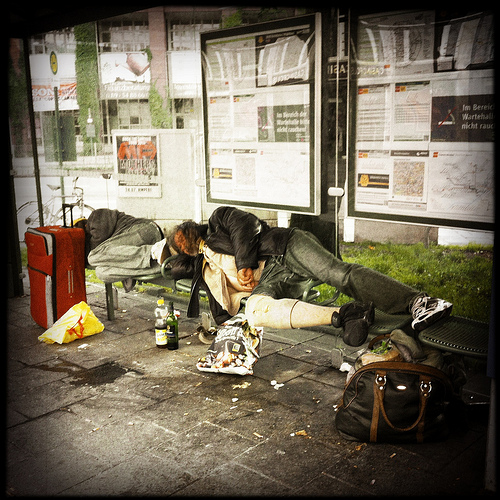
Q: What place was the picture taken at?
A: It was taken at the sidewalk.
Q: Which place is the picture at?
A: It is at the sidewalk.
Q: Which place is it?
A: It is a sidewalk.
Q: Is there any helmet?
A: No, there are no helmets.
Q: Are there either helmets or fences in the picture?
A: No, there are no helmets or fences.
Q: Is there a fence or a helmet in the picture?
A: No, there are no helmets or fences.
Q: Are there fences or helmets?
A: No, there are no helmets or fences.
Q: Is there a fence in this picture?
A: No, there are no fences.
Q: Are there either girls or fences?
A: No, there are no fences or girls.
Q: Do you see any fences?
A: No, there are no fences.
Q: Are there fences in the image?
A: No, there are no fences.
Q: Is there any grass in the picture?
A: Yes, there is grass.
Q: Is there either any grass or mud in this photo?
A: Yes, there is grass.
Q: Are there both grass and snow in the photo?
A: No, there is grass but no snow.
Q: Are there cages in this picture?
A: No, there are no cages.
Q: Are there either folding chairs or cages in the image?
A: No, there are no cages or folding chairs.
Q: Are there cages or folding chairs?
A: No, there are no cages or folding chairs.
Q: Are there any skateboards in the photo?
A: No, there are no skateboards.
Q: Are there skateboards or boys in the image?
A: No, there are no skateboards or boys.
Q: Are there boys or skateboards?
A: No, there are no skateboards or boys.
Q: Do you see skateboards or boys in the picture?
A: No, there are no skateboards or boys.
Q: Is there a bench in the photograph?
A: Yes, there is a bench.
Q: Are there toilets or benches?
A: Yes, there is a bench.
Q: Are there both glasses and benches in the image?
A: No, there is a bench but no glasses.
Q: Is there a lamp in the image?
A: No, there are no lamps.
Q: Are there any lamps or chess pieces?
A: No, there are no lamps or chess pieces.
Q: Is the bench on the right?
A: Yes, the bench is on the right of the image.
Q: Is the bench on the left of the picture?
A: No, the bench is on the right of the image.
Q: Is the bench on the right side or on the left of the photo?
A: The bench is on the right of the image.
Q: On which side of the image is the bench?
A: The bench is on the right of the image.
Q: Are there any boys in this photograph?
A: No, there are no boys.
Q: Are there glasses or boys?
A: No, there are no boys or glasses.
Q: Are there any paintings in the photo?
A: No, there are no paintings.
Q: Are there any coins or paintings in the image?
A: No, there are no paintings or coins.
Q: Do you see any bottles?
A: Yes, there is a bottle.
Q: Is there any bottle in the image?
A: Yes, there is a bottle.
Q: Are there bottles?
A: Yes, there is a bottle.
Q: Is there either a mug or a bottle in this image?
A: Yes, there is a bottle.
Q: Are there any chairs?
A: No, there are no chairs.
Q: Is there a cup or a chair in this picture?
A: No, there are no chairs or cups.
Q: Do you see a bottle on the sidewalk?
A: Yes, there is a bottle on the sidewalk.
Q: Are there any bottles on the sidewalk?
A: Yes, there is a bottle on the sidewalk.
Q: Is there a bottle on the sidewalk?
A: Yes, there is a bottle on the sidewalk.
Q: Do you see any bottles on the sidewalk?
A: Yes, there is a bottle on the sidewalk.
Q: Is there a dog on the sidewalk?
A: No, there is a bottle on the sidewalk.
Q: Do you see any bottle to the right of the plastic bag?
A: Yes, there is a bottle to the right of the bag.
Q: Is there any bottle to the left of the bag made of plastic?
A: No, the bottle is to the right of the bag.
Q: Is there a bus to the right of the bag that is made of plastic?
A: No, there is a bottle to the right of the bag.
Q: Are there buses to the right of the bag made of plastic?
A: No, there is a bottle to the right of the bag.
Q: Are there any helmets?
A: No, there are no helmets.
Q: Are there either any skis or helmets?
A: No, there are no helmets or skis.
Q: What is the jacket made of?
A: The jacket is made of leather.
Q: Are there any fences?
A: No, there are no fences.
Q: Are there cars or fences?
A: No, there are no fences or cars.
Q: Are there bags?
A: Yes, there is a bag.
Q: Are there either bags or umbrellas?
A: Yes, there is a bag.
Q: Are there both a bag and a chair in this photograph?
A: No, there is a bag but no chairs.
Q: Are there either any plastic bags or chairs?
A: Yes, there is a plastic bag.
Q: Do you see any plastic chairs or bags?
A: Yes, there is a plastic bag.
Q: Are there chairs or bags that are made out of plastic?
A: Yes, the bag is made of plastic.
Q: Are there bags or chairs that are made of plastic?
A: Yes, the bag is made of plastic.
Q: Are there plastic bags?
A: Yes, there is a bag that is made of plastic.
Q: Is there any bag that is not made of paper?
A: Yes, there is a bag that is made of plastic.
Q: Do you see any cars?
A: No, there are no cars.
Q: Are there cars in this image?
A: No, there are no cars.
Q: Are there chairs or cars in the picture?
A: No, there are no cars or chairs.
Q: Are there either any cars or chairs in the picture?
A: No, there are no cars or chairs.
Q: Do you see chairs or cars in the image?
A: No, there are no cars or chairs.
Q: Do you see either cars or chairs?
A: No, there are no cars or chairs.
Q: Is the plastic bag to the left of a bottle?
A: Yes, the bag is to the left of a bottle.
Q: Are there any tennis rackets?
A: No, there are no tennis rackets.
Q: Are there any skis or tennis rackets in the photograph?
A: No, there are no tennis rackets or skis.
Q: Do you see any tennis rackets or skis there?
A: No, there are no tennis rackets or skis.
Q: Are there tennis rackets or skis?
A: No, there are no tennis rackets or skis.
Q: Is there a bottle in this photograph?
A: Yes, there is a bottle.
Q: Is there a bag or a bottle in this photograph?
A: Yes, there is a bottle.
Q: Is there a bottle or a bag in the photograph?
A: Yes, there is a bottle.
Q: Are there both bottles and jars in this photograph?
A: No, there is a bottle but no jars.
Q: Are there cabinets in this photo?
A: No, there are no cabinets.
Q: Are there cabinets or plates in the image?
A: No, there are no cabinets or plates.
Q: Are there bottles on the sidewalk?
A: Yes, there is a bottle on the sidewalk.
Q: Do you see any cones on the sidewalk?
A: No, there is a bottle on the sidewalk.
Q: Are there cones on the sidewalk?
A: No, there is a bottle on the sidewalk.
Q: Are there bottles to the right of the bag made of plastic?
A: Yes, there is a bottle to the right of the bag.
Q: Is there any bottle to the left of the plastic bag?
A: No, the bottle is to the right of the bag.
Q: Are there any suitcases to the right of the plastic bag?
A: No, there is a bottle to the right of the bag.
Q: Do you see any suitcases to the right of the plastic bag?
A: No, there is a bottle to the right of the bag.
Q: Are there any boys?
A: No, there are no boys.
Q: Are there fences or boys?
A: No, there are no boys or fences.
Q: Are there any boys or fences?
A: No, there are no boys or fences.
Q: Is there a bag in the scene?
A: Yes, there is a bag.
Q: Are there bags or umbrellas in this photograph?
A: Yes, there is a bag.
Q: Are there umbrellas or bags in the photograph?
A: Yes, there is a bag.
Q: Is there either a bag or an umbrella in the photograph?
A: Yes, there is a bag.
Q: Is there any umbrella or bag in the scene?
A: Yes, there is a bag.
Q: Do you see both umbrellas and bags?
A: No, there is a bag but no umbrellas.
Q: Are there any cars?
A: No, there are no cars.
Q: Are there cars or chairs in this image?
A: No, there are no cars or chairs.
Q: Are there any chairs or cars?
A: No, there are no cars or chairs.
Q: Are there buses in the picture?
A: No, there are no buses.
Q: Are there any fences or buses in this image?
A: No, there are no buses or fences.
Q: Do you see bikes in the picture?
A: Yes, there is a bike.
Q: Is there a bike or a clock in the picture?
A: Yes, there is a bike.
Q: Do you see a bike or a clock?
A: Yes, there is a bike.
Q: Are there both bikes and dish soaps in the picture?
A: No, there is a bike but no dish soaps.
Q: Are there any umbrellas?
A: No, there are no umbrellas.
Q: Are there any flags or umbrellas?
A: No, there are no umbrellas or flags.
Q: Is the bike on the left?
A: Yes, the bike is on the left of the image.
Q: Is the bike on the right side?
A: No, the bike is on the left of the image.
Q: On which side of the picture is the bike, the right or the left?
A: The bike is on the left of the image.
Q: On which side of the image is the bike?
A: The bike is on the left of the image.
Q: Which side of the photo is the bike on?
A: The bike is on the left of the image.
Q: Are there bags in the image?
A: Yes, there is a bag.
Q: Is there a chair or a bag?
A: Yes, there is a bag.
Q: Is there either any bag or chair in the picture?
A: Yes, there is a bag.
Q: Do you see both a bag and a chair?
A: No, there is a bag but no chairs.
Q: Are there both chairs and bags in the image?
A: No, there is a bag but no chairs.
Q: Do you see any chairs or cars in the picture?
A: No, there are no cars or chairs.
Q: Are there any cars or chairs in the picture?
A: No, there are no cars or chairs.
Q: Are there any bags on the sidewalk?
A: Yes, there is a bag on the sidewalk.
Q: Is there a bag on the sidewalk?
A: Yes, there is a bag on the sidewalk.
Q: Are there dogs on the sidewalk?
A: No, there is a bag on the sidewalk.